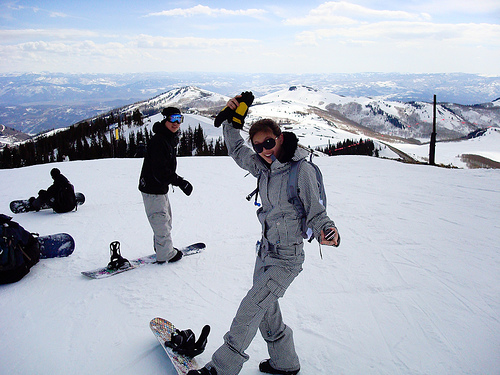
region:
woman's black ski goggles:
[244, 133, 279, 155]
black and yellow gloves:
[208, 80, 258, 132]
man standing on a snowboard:
[136, 95, 201, 270]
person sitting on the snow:
[26, 160, 83, 216]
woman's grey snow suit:
[206, 117, 329, 374]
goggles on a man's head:
[161, 110, 188, 124]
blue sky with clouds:
[1, 0, 496, 79]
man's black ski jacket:
[133, 116, 185, 196]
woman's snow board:
[148, 311, 209, 373]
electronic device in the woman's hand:
[318, 223, 336, 243]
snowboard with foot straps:
[145, 308, 216, 374]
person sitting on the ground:
[7, 165, 87, 226]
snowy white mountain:
[154, 85, 224, 101]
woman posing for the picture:
[205, 83, 366, 373]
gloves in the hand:
[211, 87, 256, 136]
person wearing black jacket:
[130, 98, 200, 269]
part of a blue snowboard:
[40, 230, 76, 260]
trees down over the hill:
[322, 133, 382, 162]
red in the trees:
[331, 140, 358, 155]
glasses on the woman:
[250, 135, 279, 159]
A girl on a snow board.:
[148, 90, 340, 374]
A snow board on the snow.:
[81, 240, 207, 278]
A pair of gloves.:
[213, 90, 255, 131]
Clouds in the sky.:
[1, 1, 498, 78]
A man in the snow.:
[138, 105, 193, 266]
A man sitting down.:
[28, 167, 77, 214]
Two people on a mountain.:
[80, 90, 340, 373]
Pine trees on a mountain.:
[2, 108, 382, 169]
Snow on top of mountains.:
[3, 69, 495, 374]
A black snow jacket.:
[138, 121, 183, 195]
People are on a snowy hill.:
[0, 51, 498, 372]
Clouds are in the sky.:
[1, 0, 492, 83]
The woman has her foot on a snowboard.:
[147, 315, 213, 373]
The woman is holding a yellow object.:
[223, 86, 255, 129]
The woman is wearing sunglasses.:
[250, 135, 275, 155]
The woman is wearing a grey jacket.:
[217, 120, 332, 245]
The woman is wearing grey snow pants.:
[203, 242, 304, 369]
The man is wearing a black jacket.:
[136, 120, 176, 193]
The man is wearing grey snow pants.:
[137, 187, 180, 263]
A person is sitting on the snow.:
[25, 166, 82, 211]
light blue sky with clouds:
[2, 0, 489, 76]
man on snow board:
[101, 111, 216, 284]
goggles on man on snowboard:
[166, 114, 186, 122]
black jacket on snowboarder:
[137, 120, 182, 201]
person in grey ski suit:
[196, 90, 317, 370]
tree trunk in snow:
[430, 98, 441, 164]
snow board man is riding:
[80, 235, 205, 277]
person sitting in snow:
[7, 168, 90, 213]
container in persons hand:
[219, 90, 253, 126]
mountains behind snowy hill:
[5, 71, 483, 156]